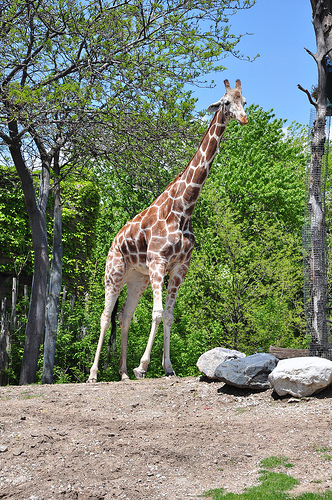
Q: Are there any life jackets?
A: No, there are no life jackets.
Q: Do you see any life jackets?
A: No, there are no life jackets.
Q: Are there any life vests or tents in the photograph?
A: No, there are no life vests or tents.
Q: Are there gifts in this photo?
A: No, there are no gifts.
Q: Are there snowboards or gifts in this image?
A: No, there are no gifts or snowboards.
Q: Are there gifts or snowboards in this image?
A: No, there are no gifts or snowboards.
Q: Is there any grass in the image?
A: Yes, there is grass.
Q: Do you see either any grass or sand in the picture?
A: Yes, there is grass.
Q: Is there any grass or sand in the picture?
A: Yes, there is grass.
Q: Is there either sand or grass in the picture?
A: Yes, there is grass.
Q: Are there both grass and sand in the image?
A: No, there is grass but no sand.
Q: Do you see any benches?
A: No, there are no benches.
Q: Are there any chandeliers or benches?
A: No, there are no benches or chandeliers.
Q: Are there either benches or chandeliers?
A: No, there are no benches or chandeliers.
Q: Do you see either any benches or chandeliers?
A: No, there are no benches or chandeliers.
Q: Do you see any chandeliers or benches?
A: No, there are no benches or chandeliers.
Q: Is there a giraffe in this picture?
A: Yes, there is a giraffe.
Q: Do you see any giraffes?
A: Yes, there is a giraffe.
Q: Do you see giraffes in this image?
A: Yes, there is a giraffe.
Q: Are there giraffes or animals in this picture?
A: Yes, there is a giraffe.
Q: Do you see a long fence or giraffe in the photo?
A: Yes, there is a long giraffe.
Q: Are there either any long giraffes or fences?
A: Yes, there is a long giraffe.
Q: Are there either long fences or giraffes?
A: Yes, there is a long giraffe.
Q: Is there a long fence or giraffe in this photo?
A: Yes, there is a long giraffe.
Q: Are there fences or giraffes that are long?
A: Yes, the giraffe is long.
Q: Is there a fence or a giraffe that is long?
A: Yes, the giraffe is long.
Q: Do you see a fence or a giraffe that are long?
A: Yes, the giraffe is long.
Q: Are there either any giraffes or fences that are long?
A: Yes, the giraffe is long.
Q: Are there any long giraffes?
A: Yes, there is a long giraffe.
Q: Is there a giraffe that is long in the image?
A: Yes, there is a long giraffe.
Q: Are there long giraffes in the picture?
A: Yes, there is a long giraffe.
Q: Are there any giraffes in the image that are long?
A: Yes, there is a giraffe that is long.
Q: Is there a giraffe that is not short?
A: Yes, there is a long giraffe.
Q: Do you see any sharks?
A: No, there are no sharks.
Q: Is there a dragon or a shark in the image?
A: No, there are no sharks or dragons.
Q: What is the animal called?
A: The animal is a giraffe.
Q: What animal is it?
A: The animal is a giraffe.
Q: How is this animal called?
A: This is a giraffe.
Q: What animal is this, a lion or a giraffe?
A: This is a giraffe.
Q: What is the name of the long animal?
A: The animal is a giraffe.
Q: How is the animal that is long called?
A: The animal is a giraffe.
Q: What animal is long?
A: The animal is a giraffe.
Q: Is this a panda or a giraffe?
A: This is a giraffe.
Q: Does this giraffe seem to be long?
A: Yes, the giraffe is long.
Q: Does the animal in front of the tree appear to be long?
A: Yes, the giraffe is long.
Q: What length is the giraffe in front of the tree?
A: The giraffe is long.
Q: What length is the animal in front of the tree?
A: The giraffe is long.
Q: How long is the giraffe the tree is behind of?
A: The giraffe is long.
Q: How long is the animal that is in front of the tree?
A: The giraffe is long.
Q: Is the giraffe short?
A: No, the giraffe is long.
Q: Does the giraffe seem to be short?
A: No, the giraffe is long.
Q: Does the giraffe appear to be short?
A: No, the giraffe is long.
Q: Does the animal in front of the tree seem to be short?
A: No, the giraffe is long.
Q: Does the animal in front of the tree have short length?
A: No, the giraffe is long.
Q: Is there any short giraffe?
A: No, there is a giraffe but it is long.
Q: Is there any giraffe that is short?
A: No, there is a giraffe but it is long.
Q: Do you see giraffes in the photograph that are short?
A: No, there is a giraffe but it is long.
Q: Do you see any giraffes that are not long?
A: No, there is a giraffe but it is long.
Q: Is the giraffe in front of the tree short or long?
A: The giraffe is long.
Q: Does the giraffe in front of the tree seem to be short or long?
A: The giraffe is long.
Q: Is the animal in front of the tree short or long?
A: The giraffe is long.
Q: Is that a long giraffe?
A: Yes, that is a long giraffe.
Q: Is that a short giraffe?
A: No, that is a long giraffe.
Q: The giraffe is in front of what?
A: The giraffe is in front of the tree.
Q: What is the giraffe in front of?
A: The giraffe is in front of the tree.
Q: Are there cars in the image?
A: No, there are no cars.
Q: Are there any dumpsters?
A: No, there are no dumpsters.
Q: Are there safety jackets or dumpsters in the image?
A: No, there are no dumpsters or safety jackets.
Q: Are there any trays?
A: No, there are no trays.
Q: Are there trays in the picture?
A: No, there are no trays.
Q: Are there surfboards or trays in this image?
A: No, there are no trays or surfboards.